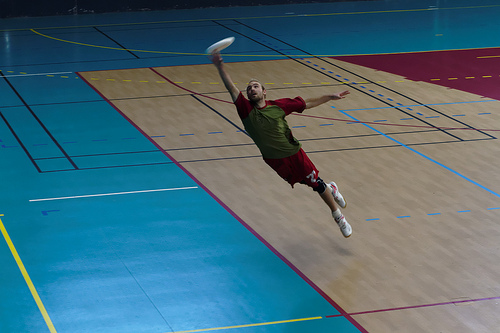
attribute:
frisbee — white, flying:
[206, 35, 234, 54]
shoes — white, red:
[328, 180, 352, 237]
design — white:
[306, 171, 318, 184]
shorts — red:
[265, 148, 319, 186]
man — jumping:
[209, 49, 354, 238]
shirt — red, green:
[233, 90, 305, 160]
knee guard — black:
[314, 178, 327, 194]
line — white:
[28, 178, 198, 209]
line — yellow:
[2, 215, 62, 330]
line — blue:
[335, 111, 498, 195]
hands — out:
[212, 49, 350, 100]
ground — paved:
[2, 1, 499, 329]